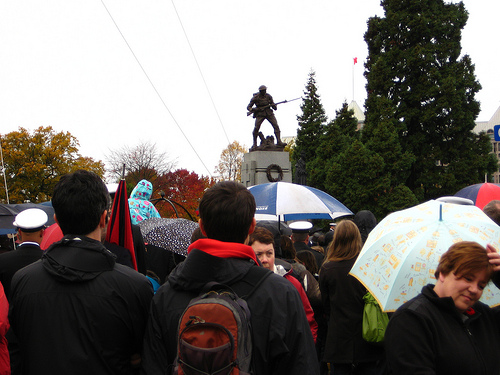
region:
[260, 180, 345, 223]
The umbrella in the picture is blue and white.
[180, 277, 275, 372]
The man is wearing a backpack.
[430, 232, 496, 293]
The lady is touching her hair.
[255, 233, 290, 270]
The lady is wearing a red sweater.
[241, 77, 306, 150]
There is a staue in the photo.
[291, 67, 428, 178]
There are green trees in the picture.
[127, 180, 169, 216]
Someone is wearing a light blue hoodie.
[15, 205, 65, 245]
The man is wearing a white hat.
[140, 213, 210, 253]
There is a purple umbrella in the picture.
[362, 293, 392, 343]
there is a light green bag in the photo.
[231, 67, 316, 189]
Statue of a soldier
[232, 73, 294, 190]
Statue is holding a gun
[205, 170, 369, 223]
Blue and white umbrella.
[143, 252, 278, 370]
Orange backpack on a back.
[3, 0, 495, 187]
The sky is bright, but grey.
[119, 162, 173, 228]
A child on someone's shoulders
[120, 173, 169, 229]
The kid is wearing a raincoat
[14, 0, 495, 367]
The weather is chilly and wet.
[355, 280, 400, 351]
Green bag on a woman's shoulder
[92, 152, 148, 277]
Closed black and red umbrella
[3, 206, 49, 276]
A member of the military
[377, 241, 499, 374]
Woman with a very short haircut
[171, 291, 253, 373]
Grey and brown backpack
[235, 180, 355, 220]
An open blue and white umbrella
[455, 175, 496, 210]
An open red and blue umbrella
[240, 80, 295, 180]
Statue honoring members of the armed forces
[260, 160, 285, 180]
A wreath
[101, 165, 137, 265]
A closed red and black umbrella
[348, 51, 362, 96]
Flag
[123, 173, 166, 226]
Child in a blue and pink jacket with the hood up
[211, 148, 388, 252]
blue and white umbrella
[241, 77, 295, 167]
statue of a soldier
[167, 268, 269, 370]
orange and black backpack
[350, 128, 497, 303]
white umbrella with yellow flowers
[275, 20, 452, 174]
evergreen trees in background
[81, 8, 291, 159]
electrical wires in photograph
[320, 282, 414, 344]
person carrying a green bag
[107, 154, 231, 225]
autumn colored trees in photo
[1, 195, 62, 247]
person with white hat on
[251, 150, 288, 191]
large circle on base of statue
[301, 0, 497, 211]
green trees next to statue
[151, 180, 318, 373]
guy wearing orange and gray backpack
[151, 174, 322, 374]
person wearing orange and black jacket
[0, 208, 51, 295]
person wearing white cap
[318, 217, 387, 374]
woman carrying green bag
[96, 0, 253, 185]
power lines above crowd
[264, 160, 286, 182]
green wreath on statue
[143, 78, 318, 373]
person in front of statue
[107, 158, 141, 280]
red umbrella with black stripes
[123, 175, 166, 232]
person wearing blue and pink jacket